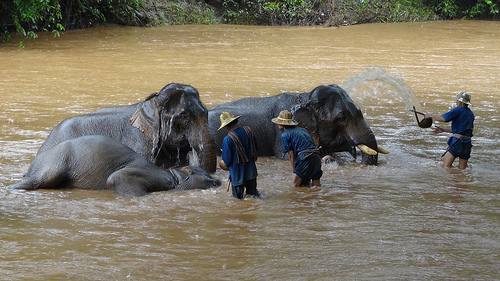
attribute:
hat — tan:
[208, 102, 241, 133]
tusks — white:
[354, 142, 393, 159]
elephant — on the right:
[213, 72, 430, 185]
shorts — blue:
[439, 131, 484, 161]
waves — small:
[385, 144, 431, 171]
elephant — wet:
[15, 48, 402, 228]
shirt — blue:
[441, 103, 481, 139]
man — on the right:
[203, 107, 268, 199]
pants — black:
[230, 175, 260, 195]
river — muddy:
[1, 18, 499, 278]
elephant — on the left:
[23, 145, 184, 205]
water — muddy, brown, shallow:
[26, 30, 496, 279]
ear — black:
[114, 98, 164, 160]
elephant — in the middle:
[30, 81, 216, 181]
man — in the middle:
[268, 109, 325, 193]